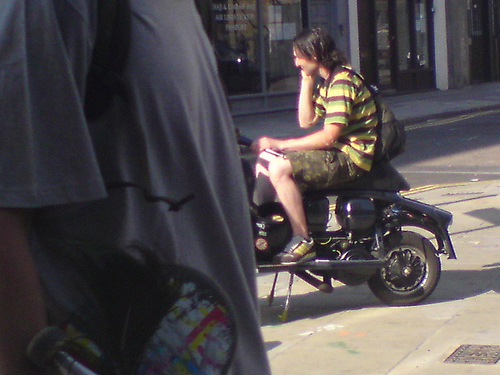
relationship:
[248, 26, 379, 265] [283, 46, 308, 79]
male talking on cellphone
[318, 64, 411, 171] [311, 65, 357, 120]
backpack on shoulders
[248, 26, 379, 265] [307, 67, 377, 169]
male wearing shirt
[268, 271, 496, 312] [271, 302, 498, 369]
shadow on pavement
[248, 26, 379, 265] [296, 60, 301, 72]
male talking on cellphone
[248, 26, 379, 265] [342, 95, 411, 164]
male wearing on backpack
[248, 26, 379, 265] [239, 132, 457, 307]
male on bike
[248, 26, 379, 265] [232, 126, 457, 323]
male on motorbike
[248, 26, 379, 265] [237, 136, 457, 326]
male on motorcycle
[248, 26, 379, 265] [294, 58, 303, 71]
male on cellphone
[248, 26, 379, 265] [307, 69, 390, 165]
male wearing shirt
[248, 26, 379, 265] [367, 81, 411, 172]
male has backpack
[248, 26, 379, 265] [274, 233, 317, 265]
male wearing tennis shoe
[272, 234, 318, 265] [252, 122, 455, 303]
tennis shoe on motorbike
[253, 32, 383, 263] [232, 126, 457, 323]
male on motorbike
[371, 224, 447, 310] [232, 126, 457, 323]
tire on motorbike